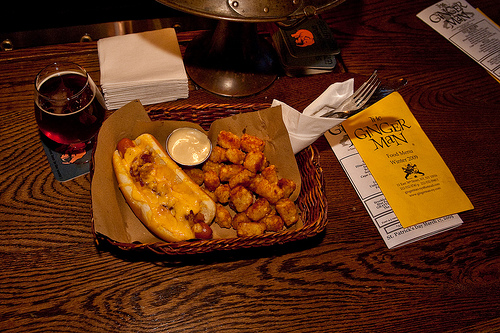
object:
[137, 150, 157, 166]
chilli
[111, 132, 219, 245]
hotdog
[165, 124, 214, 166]
tots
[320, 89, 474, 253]
menus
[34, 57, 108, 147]
glass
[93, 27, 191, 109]
napkins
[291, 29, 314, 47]
elephant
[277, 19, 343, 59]
coaster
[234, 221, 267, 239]
food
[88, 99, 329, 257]
basket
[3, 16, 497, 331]
table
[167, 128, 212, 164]
sauce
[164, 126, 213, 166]
container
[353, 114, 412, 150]
restaurant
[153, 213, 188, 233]
cheese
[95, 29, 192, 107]
stack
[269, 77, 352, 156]
napkin